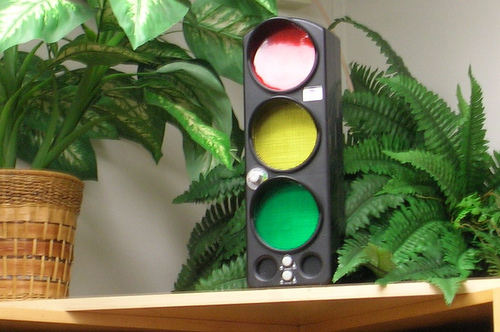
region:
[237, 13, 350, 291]
a plastic traffic light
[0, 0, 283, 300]
a brown basket with a plant in it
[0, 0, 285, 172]
the plant is green and leafy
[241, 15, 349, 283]
the lights are circular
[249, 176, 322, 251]
the light is green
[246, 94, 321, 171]
the light is yellow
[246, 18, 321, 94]
the light is red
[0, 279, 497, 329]
the shelf is light brown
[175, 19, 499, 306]
a green leafy plant behind the light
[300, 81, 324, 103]
a small sticker between the red and yellow lights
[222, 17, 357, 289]
a fake traffic light for decoration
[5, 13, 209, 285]
a plant in a wicker basket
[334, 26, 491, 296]
a fern on a shelf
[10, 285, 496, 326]
a shelf holding plants and a knicknack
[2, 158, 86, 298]
basket used as a plant holder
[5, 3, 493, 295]
plants sitting on a wooden shelf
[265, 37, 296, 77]
red lens of a stop light decoration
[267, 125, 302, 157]
a yellow plastic lens in a fake traffic light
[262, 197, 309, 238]
plastic green lens in a fake stop light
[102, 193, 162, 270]
shadow of a plant cast against a wall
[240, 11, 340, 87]
Red sign representative of a traffic light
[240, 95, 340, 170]
Yellow sign representative of a traffic light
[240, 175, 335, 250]
Green sign representative of a traffic light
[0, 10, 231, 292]
Basket of plastic plants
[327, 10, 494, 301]
Bunch of fern plants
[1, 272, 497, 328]
Wooden surface forming a rack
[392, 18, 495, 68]
Clear cream colored surface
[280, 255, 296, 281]
Pair of white buttons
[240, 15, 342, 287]
Black colored replica of traffic lights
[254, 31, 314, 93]
Bright white reflection on the surface of the red shade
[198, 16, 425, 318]
a traffic light on a table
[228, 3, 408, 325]
red yellow and green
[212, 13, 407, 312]
traffic light in black casing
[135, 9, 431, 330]
a table with light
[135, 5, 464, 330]
a table with traffic light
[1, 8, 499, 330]
a plant on a shelf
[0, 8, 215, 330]
a plant in a pot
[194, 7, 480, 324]
traffic light on shelf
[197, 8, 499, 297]
traffic light on brown shelf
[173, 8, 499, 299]
a fern behind a traffic light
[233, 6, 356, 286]
a traffic light on a table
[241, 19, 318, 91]
red part of traffic light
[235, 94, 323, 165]
yellow part of traffic light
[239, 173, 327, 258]
green part of traffic light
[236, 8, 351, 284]
traffic light is green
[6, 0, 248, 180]
a plant with big leaves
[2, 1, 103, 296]
a plant in a pot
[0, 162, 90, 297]
pot is color brown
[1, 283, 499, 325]
a wood table